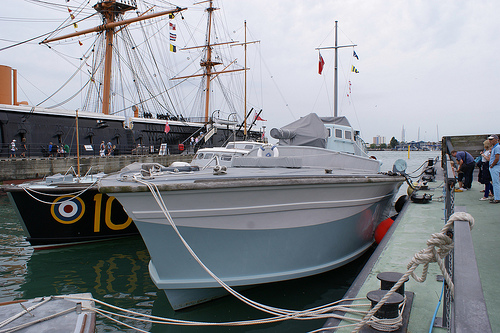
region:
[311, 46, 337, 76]
a small red flag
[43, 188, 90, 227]
a symbol on boat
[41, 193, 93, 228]
a round design on boat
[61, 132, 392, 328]
a big white steamer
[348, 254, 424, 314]
two roads placed near by steamer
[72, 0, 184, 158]
a large pillars on boat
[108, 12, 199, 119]
a small strong wires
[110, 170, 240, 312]
front part of the ship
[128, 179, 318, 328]
a strong white thread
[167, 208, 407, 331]
a thread to hold steamer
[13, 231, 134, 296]
the water is dark blue.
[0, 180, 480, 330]
the white ropes are holding the boats.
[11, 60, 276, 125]
a bunch of electricity wires.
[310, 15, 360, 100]
a pole with different flags.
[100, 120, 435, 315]
a blue and white boat.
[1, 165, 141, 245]
a black and yellow boat.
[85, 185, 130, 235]
the black boat is number 10.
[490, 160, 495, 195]
a man is wearing light blue pants.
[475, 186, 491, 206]
a woman is wearing white shoes.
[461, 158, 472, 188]
a man is wearing black pants.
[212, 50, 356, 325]
the boat is white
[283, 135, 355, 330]
the boat is white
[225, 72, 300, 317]
the boat is white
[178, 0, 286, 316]
the boat is white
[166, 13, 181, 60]
small different flags visible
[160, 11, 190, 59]
small different flags visible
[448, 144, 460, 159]
the head of a man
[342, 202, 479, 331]
a white rope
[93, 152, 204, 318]
the bow of a boat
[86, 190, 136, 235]
a yellow number on the boat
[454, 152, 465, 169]
the arm of a man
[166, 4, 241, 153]
the mast of a ship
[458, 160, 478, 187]
the legs of a man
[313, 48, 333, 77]
a flag on the boat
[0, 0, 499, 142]
a cloudy gray sky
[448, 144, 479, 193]
a man on the dock